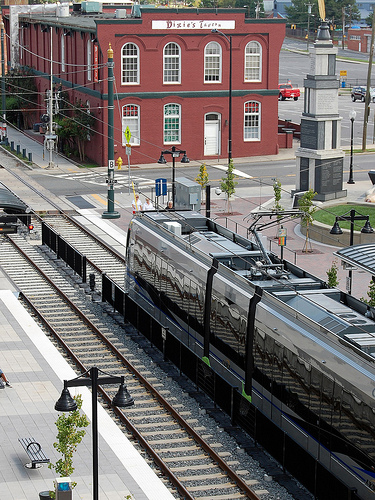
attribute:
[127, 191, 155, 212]
people — walking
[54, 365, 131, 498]
street light — black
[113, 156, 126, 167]
hydrants — yellow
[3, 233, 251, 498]
train track — set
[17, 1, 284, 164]
building — red, Dixie's Tavern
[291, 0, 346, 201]
statue — concrete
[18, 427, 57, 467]
bench — wood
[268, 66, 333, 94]
truck — red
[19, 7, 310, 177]
building — large, red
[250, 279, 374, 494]
train engine — grey, blue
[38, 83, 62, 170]
signal — crossing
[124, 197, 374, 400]
train — silver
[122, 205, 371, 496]
train — grey, blue